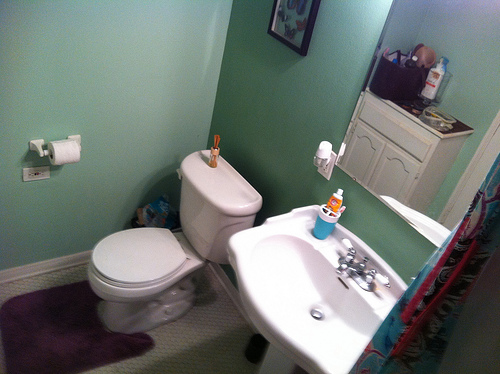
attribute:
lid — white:
[91, 225, 189, 280]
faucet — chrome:
[338, 236, 360, 263]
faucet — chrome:
[366, 266, 390, 293]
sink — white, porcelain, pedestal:
[226, 202, 404, 371]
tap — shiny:
[330, 233, 391, 297]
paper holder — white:
[28, 134, 81, 158]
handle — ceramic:
[371, 270, 390, 287]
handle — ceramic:
[340, 237, 356, 255]